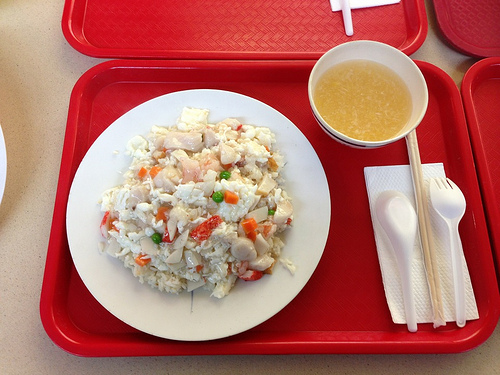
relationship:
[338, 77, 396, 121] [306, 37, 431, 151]
soup in bowl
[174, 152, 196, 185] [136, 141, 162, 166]
chicken with rice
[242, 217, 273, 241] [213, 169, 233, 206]
carrots and peas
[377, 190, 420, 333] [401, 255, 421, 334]
spoon has handle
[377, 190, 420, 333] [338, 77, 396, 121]
spoon for soup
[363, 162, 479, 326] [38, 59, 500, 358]
napkin on tray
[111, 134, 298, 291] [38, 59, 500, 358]
meal on tray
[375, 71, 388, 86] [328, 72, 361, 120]
particles in broth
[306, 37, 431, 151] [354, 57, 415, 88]
bowl has inside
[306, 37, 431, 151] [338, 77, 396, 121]
bowl of soup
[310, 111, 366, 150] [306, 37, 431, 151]
line on bowl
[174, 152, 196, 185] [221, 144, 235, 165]
chicken in chunk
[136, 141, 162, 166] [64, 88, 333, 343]
rice on plate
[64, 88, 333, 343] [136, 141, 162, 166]
plate with heaping rice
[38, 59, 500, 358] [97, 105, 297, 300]
tray with meal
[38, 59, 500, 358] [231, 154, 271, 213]
tray with food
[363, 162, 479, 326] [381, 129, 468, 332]
napkin with utensils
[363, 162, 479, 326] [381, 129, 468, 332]
napkin has utensils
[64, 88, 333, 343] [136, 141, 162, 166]
plate with rice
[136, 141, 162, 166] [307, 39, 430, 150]
rice in bowl